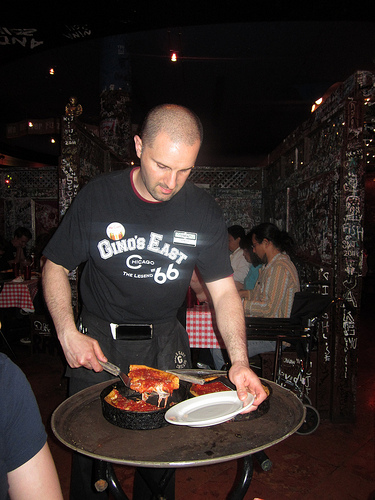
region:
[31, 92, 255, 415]
man in a black shirt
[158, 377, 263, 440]
white plate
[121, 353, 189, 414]
slice of pepperoni pizza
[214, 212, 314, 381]
man sitting in a chair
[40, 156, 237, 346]
black t-shirt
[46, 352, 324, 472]
pizza being put on a plate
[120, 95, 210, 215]
man with short hair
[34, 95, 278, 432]
man working in a pizza parlor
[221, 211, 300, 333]
man in a striped shirt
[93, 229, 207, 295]
Gino's East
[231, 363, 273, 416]
the hand of the man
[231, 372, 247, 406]
the thumb of the man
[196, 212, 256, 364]
the arm of the man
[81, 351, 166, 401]
a spatula in the man's hand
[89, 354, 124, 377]
the wooden handle of the spatula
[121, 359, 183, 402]
a piece of pizza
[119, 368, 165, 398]
the metal spatula end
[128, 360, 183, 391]
the crust of the pizza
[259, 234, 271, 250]
the ear of the man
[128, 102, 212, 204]
the head of the man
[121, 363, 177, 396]
pizza on a spatula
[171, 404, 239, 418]
white plate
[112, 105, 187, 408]
waiter serving pizza in a restaurant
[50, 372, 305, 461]
brown circular tray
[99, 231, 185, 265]
white logo for Gino's East Chicago on a black shirt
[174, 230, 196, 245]
restaurant employee's name tag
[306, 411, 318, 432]
back wheel of a wheelchair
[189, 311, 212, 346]
red and white checkered tablecloth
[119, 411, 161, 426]
black pizza pan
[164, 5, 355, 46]
night sky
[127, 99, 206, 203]
THE HEAD OF A PERSON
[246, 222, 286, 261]
THE HEAD OF A PERSON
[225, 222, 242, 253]
THE HEAD OF A PERSON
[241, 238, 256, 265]
THE HEAD OF A PERSON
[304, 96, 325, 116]
the light that is on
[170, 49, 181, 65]
the light that is on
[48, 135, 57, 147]
the light that is on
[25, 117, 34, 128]
the light that is on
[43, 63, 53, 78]
the light that is on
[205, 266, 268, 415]
the hand of a person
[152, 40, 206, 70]
small light in the overhead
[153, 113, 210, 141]
man's short hair cut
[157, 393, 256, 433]
white plate in man's hand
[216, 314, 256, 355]
hair on man's arm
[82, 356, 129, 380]
brown wooden handle of pizza slicer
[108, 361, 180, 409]
large slice of pizza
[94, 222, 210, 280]
white words on black shirt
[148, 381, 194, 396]
gooey white cheese on pizza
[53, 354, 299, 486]
large rusted round black tray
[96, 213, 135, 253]
white circle on black tee shirt